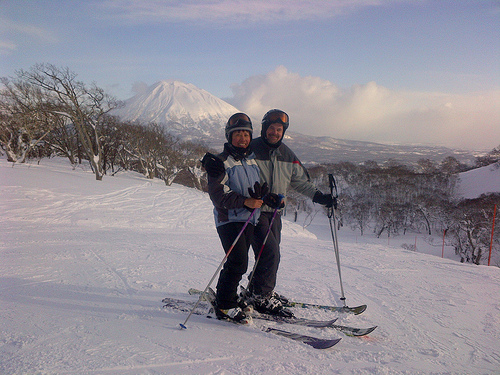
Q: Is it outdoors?
A: Yes, it is outdoors.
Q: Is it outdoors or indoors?
A: It is outdoors.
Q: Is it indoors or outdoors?
A: It is outdoors.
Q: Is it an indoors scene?
A: No, it is outdoors.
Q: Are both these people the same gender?
A: No, they are both male and female.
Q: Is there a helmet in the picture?
A: Yes, there is a helmet.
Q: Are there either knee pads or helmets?
A: Yes, there is a helmet.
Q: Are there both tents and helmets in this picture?
A: No, there is a helmet but no tents.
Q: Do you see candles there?
A: No, there are no candles.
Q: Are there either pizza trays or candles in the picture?
A: No, there are no candles or pizza trays.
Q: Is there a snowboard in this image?
A: No, there are no snowboards.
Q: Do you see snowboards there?
A: No, there are no snowboards.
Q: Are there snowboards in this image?
A: No, there are no snowboards.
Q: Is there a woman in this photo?
A: Yes, there is a woman.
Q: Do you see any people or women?
A: Yes, there is a woman.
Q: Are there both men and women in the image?
A: Yes, there are both a woman and a man.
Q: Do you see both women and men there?
A: Yes, there are both a woman and a man.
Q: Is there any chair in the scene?
A: No, there are no chairs.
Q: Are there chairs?
A: No, there are no chairs.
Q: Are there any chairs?
A: No, there are no chairs.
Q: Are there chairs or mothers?
A: No, there are no chairs or mothers.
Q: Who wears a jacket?
A: The woman wears a jacket.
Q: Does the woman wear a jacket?
A: Yes, the woman wears a jacket.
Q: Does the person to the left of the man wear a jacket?
A: Yes, the woman wears a jacket.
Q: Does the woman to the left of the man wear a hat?
A: No, the woman wears a jacket.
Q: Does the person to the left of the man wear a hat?
A: No, the woman wears a jacket.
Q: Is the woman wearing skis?
A: Yes, the woman is wearing skis.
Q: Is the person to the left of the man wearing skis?
A: Yes, the woman is wearing skis.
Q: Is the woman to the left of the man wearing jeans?
A: No, the woman is wearing skis.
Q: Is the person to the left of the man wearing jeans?
A: No, the woman is wearing skis.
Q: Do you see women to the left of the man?
A: Yes, there is a woman to the left of the man.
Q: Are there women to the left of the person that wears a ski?
A: Yes, there is a woman to the left of the man.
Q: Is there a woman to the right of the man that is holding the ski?
A: No, the woman is to the left of the man.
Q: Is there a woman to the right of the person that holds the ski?
A: No, the woman is to the left of the man.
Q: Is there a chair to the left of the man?
A: No, there is a woman to the left of the man.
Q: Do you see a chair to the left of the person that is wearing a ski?
A: No, there is a woman to the left of the man.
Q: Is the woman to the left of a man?
A: Yes, the woman is to the left of a man.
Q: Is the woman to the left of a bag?
A: No, the woman is to the left of a man.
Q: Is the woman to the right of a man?
A: No, the woman is to the left of a man.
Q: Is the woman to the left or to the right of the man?
A: The woman is to the left of the man.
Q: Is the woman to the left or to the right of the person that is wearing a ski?
A: The woman is to the left of the man.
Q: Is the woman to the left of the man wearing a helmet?
A: Yes, the woman is wearing a helmet.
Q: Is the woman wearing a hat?
A: No, the woman is wearing a helmet.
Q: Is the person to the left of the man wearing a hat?
A: No, the woman is wearing a helmet.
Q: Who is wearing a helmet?
A: The woman is wearing a helmet.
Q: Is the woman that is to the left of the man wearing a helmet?
A: Yes, the woman is wearing a helmet.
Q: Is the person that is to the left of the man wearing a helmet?
A: Yes, the woman is wearing a helmet.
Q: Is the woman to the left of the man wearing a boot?
A: No, the woman is wearing a helmet.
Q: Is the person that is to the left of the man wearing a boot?
A: No, the woman is wearing a helmet.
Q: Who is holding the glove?
A: The woman is holding the glove.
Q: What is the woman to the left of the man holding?
A: The woman is holding the glove.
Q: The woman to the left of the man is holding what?
A: The woman is holding the glove.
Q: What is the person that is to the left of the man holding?
A: The woman is holding the glove.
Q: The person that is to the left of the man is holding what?
A: The woman is holding the glove.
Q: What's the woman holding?
A: The woman is holding the glove.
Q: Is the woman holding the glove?
A: Yes, the woman is holding the glove.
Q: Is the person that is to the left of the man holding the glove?
A: Yes, the woman is holding the glove.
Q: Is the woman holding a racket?
A: No, the woman is holding the glove.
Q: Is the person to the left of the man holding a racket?
A: No, the woman is holding the glove.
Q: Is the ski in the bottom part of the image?
A: Yes, the ski is in the bottom of the image.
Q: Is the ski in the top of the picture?
A: No, the ski is in the bottom of the image.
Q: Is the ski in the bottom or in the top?
A: The ski is in the bottom of the image.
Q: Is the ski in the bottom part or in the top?
A: The ski is in the bottom of the image.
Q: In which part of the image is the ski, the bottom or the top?
A: The ski is in the bottom of the image.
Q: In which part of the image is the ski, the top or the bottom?
A: The ski is in the bottom of the image.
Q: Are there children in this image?
A: No, there are no children.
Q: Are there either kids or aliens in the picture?
A: No, there are no kids or aliens.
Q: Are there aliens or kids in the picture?
A: No, there are no kids or aliens.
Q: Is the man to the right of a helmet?
A: Yes, the man is to the right of a helmet.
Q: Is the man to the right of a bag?
A: No, the man is to the right of a helmet.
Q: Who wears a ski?
A: The man wears a ski.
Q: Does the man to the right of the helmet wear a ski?
A: Yes, the man wears a ski.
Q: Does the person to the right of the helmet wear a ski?
A: Yes, the man wears a ski.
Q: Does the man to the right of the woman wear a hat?
A: No, the man wears a ski.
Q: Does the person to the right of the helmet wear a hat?
A: No, the man wears a ski.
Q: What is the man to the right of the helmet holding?
A: The man is holding the ski.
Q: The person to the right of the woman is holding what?
A: The man is holding the ski.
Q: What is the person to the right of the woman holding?
A: The man is holding the ski.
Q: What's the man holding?
A: The man is holding the ski.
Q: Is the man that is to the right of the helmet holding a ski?
A: Yes, the man is holding a ski.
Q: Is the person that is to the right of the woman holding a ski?
A: Yes, the man is holding a ski.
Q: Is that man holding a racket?
A: No, the man is holding a ski.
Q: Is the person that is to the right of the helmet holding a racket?
A: No, the man is holding a ski.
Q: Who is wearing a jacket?
A: The man is wearing a jacket.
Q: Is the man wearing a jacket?
A: Yes, the man is wearing a jacket.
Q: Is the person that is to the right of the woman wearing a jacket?
A: Yes, the man is wearing a jacket.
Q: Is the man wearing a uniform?
A: No, the man is wearing a jacket.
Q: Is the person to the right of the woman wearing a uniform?
A: No, the man is wearing a jacket.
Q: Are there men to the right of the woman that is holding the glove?
A: Yes, there is a man to the right of the woman.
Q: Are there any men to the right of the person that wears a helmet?
A: Yes, there is a man to the right of the woman.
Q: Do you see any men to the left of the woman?
A: No, the man is to the right of the woman.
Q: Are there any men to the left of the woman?
A: No, the man is to the right of the woman.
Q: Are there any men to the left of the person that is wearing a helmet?
A: No, the man is to the right of the woman.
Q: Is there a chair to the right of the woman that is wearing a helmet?
A: No, there is a man to the right of the woman.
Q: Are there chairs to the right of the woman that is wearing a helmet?
A: No, there is a man to the right of the woman.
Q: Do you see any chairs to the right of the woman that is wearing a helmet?
A: No, there is a man to the right of the woman.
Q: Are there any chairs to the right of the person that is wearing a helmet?
A: No, there is a man to the right of the woman.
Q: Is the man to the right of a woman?
A: Yes, the man is to the right of a woman.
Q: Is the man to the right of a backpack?
A: No, the man is to the right of a woman.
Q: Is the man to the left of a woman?
A: No, the man is to the right of a woman.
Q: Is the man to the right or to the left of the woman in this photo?
A: The man is to the right of the woman.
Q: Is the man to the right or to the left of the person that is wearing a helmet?
A: The man is to the right of the woman.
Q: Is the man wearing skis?
A: Yes, the man is wearing skis.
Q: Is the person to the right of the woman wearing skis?
A: Yes, the man is wearing skis.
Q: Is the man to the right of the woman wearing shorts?
A: No, the man is wearing skis.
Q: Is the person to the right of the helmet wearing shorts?
A: No, the man is wearing skis.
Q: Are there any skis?
A: Yes, there are skis.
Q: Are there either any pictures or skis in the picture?
A: Yes, there are skis.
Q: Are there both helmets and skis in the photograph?
A: Yes, there are both skis and a helmet.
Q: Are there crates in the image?
A: No, there are no crates.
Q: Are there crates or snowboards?
A: No, there are no crates or snowboards.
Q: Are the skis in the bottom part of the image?
A: Yes, the skis are in the bottom of the image.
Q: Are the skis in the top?
A: No, the skis are in the bottom of the image.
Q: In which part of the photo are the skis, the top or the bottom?
A: The skis are in the bottom of the image.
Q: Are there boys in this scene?
A: No, there are no boys.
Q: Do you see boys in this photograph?
A: No, there are no boys.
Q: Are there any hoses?
A: No, there are no hoses.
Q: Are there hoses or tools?
A: No, there are no hoses or tools.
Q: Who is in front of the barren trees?
A: The couple is in front of the trees.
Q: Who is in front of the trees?
A: The couple is in front of the trees.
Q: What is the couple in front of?
A: The couple is in front of the trees.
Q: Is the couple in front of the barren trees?
A: Yes, the couple is in front of the trees.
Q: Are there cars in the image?
A: No, there are no cars.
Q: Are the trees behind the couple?
A: Yes, the trees are behind the couple.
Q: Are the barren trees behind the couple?
A: Yes, the trees are behind the couple.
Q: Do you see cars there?
A: No, there are no cars.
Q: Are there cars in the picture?
A: No, there are no cars.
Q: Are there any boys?
A: No, there are no boys.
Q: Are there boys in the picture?
A: No, there are no boys.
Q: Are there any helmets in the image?
A: Yes, there is a helmet.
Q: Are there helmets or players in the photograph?
A: Yes, there is a helmet.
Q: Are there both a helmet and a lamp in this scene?
A: No, there is a helmet but no lamps.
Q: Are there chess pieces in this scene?
A: No, there are no chess pieces.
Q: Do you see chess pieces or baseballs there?
A: No, there are no chess pieces or baseballs.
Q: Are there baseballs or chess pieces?
A: No, there are no chess pieces or baseballs.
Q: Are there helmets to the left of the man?
A: Yes, there is a helmet to the left of the man.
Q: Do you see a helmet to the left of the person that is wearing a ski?
A: Yes, there is a helmet to the left of the man.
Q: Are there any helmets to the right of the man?
A: No, the helmet is to the left of the man.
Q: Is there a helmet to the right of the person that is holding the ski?
A: No, the helmet is to the left of the man.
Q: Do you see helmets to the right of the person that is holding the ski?
A: No, the helmet is to the left of the man.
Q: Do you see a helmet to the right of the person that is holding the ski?
A: No, the helmet is to the left of the man.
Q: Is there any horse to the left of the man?
A: No, there is a helmet to the left of the man.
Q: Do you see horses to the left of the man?
A: No, there is a helmet to the left of the man.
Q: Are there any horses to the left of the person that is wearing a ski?
A: No, there is a helmet to the left of the man.